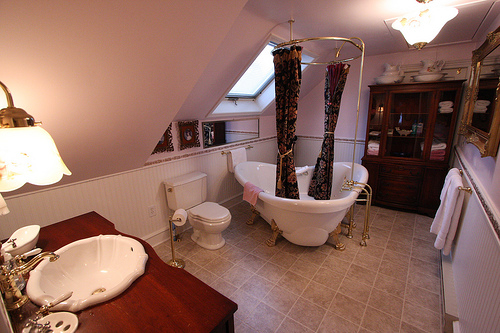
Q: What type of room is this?
A: It is a bathroom.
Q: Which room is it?
A: It is a bathroom.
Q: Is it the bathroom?
A: Yes, it is the bathroom.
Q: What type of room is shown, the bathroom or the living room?
A: It is the bathroom.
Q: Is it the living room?
A: No, it is the bathroom.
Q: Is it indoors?
A: Yes, it is indoors.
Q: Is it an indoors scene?
A: Yes, it is indoors.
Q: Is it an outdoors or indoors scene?
A: It is indoors.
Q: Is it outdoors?
A: No, it is indoors.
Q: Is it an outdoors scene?
A: No, it is indoors.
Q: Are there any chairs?
A: No, there are no chairs.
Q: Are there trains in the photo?
A: No, there are no trains.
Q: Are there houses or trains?
A: No, there are no trains or houses.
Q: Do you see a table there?
A: Yes, there is a table.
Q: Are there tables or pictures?
A: Yes, there is a table.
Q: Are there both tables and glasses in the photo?
A: No, there is a table but no glasses.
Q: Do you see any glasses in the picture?
A: No, there are no glasses.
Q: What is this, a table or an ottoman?
A: This is a table.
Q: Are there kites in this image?
A: No, there are no kites.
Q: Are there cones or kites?
A: No, there are no kites or cones.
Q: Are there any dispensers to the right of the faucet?
A: Yes, there is a dispenser to the right of the faucet.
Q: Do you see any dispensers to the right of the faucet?
A: Yes, there is a dispenser to the right of the faucet.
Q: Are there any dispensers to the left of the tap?
A: No, the dispenser is to the right of the tap.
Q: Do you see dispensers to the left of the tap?
A: No, the dispenser is to the right of the tap.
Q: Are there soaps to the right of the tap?
A: No, there is a dispenser to the right of the tap.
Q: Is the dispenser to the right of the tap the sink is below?
A: Yes, the dispenser is to the right of the tap.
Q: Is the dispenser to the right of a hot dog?
A: No, the dispenser is to the right of the tap.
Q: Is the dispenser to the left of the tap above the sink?
A: No, the dispenser is to the right of the tap.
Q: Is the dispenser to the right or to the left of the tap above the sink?
A: The dispenser is to the right of the tap.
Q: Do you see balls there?
A: No, there are no balls.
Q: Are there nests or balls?
A: No, there are no balls or nests.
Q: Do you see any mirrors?
A: Yes, there is a mirror.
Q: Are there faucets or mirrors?
A: Yes, there is a mirror.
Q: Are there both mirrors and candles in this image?
A: No, there is a mirror but no candles.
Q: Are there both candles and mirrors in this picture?
A: No, there is a mirror but no candles.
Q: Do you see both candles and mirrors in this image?
A: No, there is a mirror but no candles.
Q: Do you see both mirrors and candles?
A: No, there is a mirror but no candles.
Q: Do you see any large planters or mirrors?
A: Yes, there is a large mirror.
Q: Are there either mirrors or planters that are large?
A: Yes, the mirror is large.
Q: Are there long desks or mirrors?
A: Yes, there is a long mirror.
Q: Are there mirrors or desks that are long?
A: Yes, the mirror is long.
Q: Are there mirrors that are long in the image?
A: Yes, there is a long mirror.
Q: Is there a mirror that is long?
A: Yes, there is a mirror that is long.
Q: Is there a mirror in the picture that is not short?
A: Yes, there is a long mirror.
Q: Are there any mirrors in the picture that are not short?
A: Yes, there is a long mirror.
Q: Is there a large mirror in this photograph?
A: Yes, there is a large mirror.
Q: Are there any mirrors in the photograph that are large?
A: Yes, there is a mirror that is large.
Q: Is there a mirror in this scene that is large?
A: Yes, there is a mirror that is large.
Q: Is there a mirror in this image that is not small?
A: Yes, there is a large mirror.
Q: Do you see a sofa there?
A: No, there are no sofas.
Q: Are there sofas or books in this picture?
A: No, there are no sofas or books.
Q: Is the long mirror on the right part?
A: Yes, the mirror is on the right of the image.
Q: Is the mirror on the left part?
A: No, the mirror is on the right of the image.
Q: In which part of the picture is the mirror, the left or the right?
A: The mirror is on the right of the image.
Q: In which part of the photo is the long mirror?
A: The mirror is on the right of the image.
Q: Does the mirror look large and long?
A: Yes, the mirror is large and long.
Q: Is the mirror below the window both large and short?
A: No, the mirror is large but long.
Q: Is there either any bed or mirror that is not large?
A: No, there is a mirror but it is large.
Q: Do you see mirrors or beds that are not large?
A: No, there is a mirror but it is large.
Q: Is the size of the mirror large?
A: Yes, the mirror is large.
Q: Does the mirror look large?
A: Yes, the mirror is large.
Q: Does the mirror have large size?
A: Yes, the mirror is large.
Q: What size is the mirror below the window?
A: The mirror is large.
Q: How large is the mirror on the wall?
A: The mirror is large.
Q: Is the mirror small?
A: No, the mirror is large.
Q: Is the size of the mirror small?
A: No, the mirror is large.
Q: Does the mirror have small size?
A: No, the mirror is large.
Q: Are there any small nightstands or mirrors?
A: No, there is a mirror but it is large.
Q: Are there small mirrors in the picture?
A: No, there is a mirror but it is large.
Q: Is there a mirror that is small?
A: No, there is a mirror but it is large.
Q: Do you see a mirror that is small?
A: No, there is a mirror but it is large.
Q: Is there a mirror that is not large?
A: No, there is a mirror but it is large.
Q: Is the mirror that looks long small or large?
A: The mirror is large.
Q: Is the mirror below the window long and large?
A: Yes, the mirror is long and large.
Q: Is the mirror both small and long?
A: No, the mirror is long but large.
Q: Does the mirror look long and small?
A: No, the mirror is long but large.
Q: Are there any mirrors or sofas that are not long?
A: No, there is a mirror but it is long.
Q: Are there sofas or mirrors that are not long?
A: No, there is a mirror but it is long.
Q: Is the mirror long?
A: Yes, the mirror is long.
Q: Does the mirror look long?
A: Yes, the mirror is long.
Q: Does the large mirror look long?
A: Yes, the mirror is long.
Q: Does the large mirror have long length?
A: Yes, the mirror is long.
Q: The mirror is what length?
A: The mirror is long.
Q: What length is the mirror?
A: The mirror is long.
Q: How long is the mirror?
A: The mirror is long.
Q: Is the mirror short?
A: No, the mirror is long.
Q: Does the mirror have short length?
A: No, the mirror is long.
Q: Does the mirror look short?
A: No, the mirror is long.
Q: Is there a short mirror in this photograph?
A: No, there is a mirror but it is long.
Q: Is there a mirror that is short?
A: No, there is a mirror but it is long.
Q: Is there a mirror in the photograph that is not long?
A: No, there is a mirror but it is long.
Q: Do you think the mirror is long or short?
A: The mirror is long.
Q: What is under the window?
A: The mirror is under the window.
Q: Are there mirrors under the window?
A: Yes, there is a mirror under the window.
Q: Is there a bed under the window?
A: No, there is a mirror under the window.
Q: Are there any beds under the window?
A: No, there is a mirror under the window.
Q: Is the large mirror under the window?
A: Yes, the mirror is under the window.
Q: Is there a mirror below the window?
A: Yes, there is a mirror below the window.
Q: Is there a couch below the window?
A: No, there is a mirror below the window.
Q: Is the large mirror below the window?
A: Yes, the mirror is below the window.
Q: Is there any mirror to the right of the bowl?
A: Yes, there is a mirror to the right of the bowl.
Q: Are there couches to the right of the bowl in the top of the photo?
A: No, there is a mirror to the right of the bowl.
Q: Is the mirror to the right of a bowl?
A: Yes, the mirror is to the right of a bowl.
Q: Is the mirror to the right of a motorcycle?
A: No, the mirror is to the right of a bowl.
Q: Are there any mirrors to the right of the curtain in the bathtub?
A: Yes, there is a mirror to the right of the curtain.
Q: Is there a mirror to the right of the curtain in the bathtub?
A: Yes, there is a mirror to the right of the curtain.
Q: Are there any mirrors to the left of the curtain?
A: No, the mirror is to the right of the curtain.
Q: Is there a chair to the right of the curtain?
A: No, there is a mirror to the right of the curtain.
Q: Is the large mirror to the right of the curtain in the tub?
A: Yes, the mirror is to the right of the curtain.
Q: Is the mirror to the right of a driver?
A: No, the mirror is to the right of the curtain.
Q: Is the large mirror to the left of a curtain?
A: No, the mirror is to the right of a curtain.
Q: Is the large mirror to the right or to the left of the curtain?
A: The mirror is to the right of the curtain.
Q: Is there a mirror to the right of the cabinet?
A: Yes, there is a mirror to the right of the cabinet.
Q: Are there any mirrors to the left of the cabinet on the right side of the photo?
A: No, the mirror is to the right of the cabinet.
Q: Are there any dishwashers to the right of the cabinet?
A: No, there is a mirror to the right of the cabinet.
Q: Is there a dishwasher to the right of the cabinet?
A: No, there is a mirror to the right of the cabinet.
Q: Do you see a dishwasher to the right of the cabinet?
A: No, there is a mirror to the right of the cabinet.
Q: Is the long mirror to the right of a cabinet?
A: Yes, the mirror is to the right of a cabinet.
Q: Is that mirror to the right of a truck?
A: No, the mirror is to the right of a cabinet.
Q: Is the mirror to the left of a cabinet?
A: No, the mirror is to the right of a cabinet.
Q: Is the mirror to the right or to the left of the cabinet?
A: The mirror is to the right of the cabinet.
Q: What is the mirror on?
A: The mirror is on the wall.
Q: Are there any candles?
A: No, there are no candles.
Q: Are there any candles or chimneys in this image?
A: No, there are no candles or chimneys.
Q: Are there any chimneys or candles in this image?
A: No, there are no candles or chimneys.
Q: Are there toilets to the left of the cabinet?
A: Yes, there is a toilet to the left of the cabinet.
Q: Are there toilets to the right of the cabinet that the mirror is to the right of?
A: No, the toilet is to the left of the cabinet.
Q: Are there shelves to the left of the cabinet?
A: No, there is a toilet to the left of the cabinet.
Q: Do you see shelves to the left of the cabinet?
A: No, there is a toilet to the left of the cabinet.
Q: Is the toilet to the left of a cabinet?
A: Yes, the toilet is to the left of a cabinet.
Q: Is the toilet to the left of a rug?
A: No, the toilet is to the left of a cabinet.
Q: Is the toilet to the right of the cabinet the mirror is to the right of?
A: No, the toilet is to the left of the cabinet.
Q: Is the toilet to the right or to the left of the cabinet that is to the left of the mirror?
A: The toilet is to the left of the cabinet.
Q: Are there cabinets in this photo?
A: Yes, there is a cabinet.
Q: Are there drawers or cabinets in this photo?
A: Yes, there is a cabinet.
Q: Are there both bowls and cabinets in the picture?
A: Yes, there are both a cabinet and a bowl.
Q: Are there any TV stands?
A: No, there are no TV stands.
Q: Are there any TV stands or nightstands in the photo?
A: No, there are no TV stands or nightstands.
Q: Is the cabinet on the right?
A: Yes, the cabinet is on the right of the image.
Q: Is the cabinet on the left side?
A: No, the cabinet is on the right of the image.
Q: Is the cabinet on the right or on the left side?
A: The cabinet is on the right of the image.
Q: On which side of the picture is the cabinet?
A: The cabinet is on the right of the image.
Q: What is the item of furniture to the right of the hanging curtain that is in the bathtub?
A: The piece of furniture is a cabinet.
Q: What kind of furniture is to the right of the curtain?
A: The piece of furniture is a cabinet.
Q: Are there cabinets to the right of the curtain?
A: Yes, there is a cabinet to the right of the curtain.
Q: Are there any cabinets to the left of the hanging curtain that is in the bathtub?
A: No, the cabinet is to the right of the curtain.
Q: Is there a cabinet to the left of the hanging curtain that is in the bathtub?
A: No, the cabinet is to the right of the curtain.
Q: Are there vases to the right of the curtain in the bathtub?
A: No, there is a cabinet to the right of the curtain.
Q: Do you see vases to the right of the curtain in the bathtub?
A: No, there is a cabinet to the right of the curtain.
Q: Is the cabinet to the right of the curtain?
A: Yes, the cabinet is to the right of the curtain.